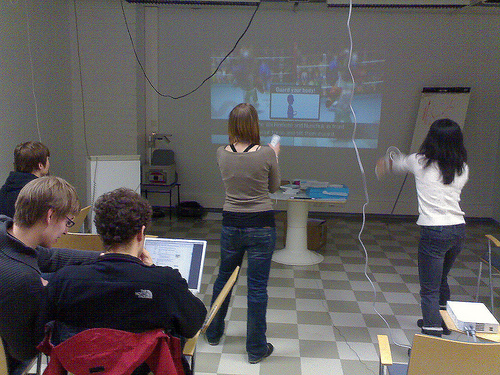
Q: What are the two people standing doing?
A: Playing game.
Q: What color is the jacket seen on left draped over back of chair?
A: Red.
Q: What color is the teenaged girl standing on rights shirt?
A: White.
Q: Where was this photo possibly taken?
A: Classroom.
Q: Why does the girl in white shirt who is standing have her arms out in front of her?
A: Operating game control.